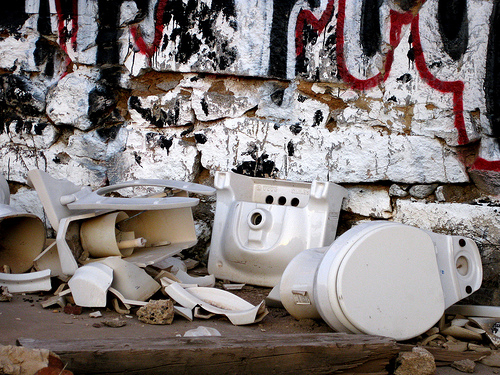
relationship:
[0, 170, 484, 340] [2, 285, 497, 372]
ceramic on ground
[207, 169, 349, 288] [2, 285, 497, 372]
sink on ground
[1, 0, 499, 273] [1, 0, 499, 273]
background in background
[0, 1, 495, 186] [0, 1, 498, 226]
graffiti on wall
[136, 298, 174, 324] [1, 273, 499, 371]
rock on ground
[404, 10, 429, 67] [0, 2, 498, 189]
coloring on wall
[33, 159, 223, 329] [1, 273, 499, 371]
toilet laying on ground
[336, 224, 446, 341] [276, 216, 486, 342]
lid on toilet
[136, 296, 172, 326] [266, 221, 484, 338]
rock beside toilet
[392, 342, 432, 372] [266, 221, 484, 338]
rock beside toilet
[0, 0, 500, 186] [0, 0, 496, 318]
graffiti on wall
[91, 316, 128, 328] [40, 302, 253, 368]
rock on ground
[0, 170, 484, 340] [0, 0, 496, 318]
ceramic near a wall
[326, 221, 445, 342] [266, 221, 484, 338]
toilet`s seat of toilet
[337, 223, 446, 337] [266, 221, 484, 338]
lid on toilet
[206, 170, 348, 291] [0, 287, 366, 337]
sink on ground